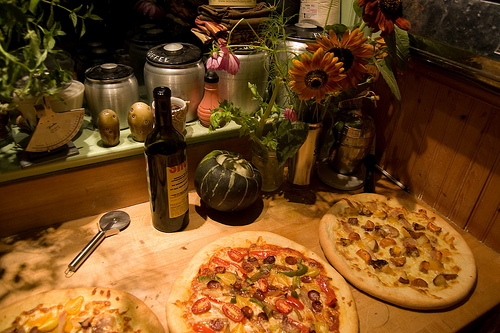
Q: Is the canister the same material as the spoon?
A: Yes, both the canister and the spoon are made of metal.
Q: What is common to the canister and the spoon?
A: The material, both the canister and the spoon are metallic.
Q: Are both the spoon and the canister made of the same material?
A: Yes, both the spoon and the canister are made of metal.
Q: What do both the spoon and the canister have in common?
A: The material, both the spoon and the canister are metallic.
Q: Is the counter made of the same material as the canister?
A: No, the counter is made of wood and the canister is made of metal.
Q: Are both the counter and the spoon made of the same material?
A: No, the counter is made of wood and the spoon is made of metal.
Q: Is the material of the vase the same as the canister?
A: No, the vase is made of glass and the canister is made of metal.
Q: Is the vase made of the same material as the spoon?
A: No, the vase is made of glass and the spoon is made of metal.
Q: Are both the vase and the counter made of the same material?
A: No, the vase is made of glass and the counter is made of wood.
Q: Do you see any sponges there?
A: No, there are no sponges.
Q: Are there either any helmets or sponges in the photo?
A: No, there are no sponges or helmets.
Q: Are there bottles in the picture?
A: Yes, there is a bottle.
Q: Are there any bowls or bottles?
A: Yes, there is a bottle.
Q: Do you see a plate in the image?
A: No, there are no plates.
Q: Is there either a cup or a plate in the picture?
A: No, there are no plates or cups.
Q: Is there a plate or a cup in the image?
A: No, there are no plates or cups.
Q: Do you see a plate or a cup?
A: No, there are no plates or cups.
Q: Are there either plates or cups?
A: No, there are no plates or cups.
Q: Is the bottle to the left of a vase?
A: Yes, the bottle is to the left of a vase.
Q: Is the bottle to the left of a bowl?
A: No, the bottle is to the left of a vase.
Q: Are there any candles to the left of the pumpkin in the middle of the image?
A: No, there is a bottle to the left of the pumpkin.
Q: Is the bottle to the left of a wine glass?
A: No, the bottle is to the left of the pumpkin.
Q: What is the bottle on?
A: The bottle is on the counter.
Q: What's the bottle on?
A: The bottle is on the counter.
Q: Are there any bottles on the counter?
A: Yes, there is a bottle on the counter.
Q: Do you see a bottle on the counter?
A: Yes, there is a bottle on the counter.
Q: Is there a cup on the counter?
A: No, there is a bottle on the counter.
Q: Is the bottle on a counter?
A: Yes, the bottle is on a counter.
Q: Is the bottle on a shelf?
A: No, the bottle is on a counter.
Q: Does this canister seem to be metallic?
A: Yes, the canister is metallic.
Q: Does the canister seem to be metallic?
A: Yes, the canister is metallic.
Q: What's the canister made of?
A: The canister is made of metal.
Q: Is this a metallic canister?
A: Yes, this is a metallic canister.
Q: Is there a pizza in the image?
A: Yes, there is a pizza.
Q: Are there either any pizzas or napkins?
A: Yes, there is a pizza.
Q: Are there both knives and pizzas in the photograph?
A: No, there is a pizza but no knives.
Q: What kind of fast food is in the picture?
A: The fast food is a pizza.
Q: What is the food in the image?
A: The food is a pizza.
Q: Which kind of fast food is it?
A: The food is a pizza.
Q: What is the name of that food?
A: This is a pizza.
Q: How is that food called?
A: This is a pizza.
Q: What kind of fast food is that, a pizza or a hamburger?
A: This is a pizza.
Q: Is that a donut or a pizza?
A: That is a pizza.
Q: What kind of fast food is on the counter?
A: The food is a pizza.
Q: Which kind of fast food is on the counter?
A: The food is a pizza.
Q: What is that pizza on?
A: The pizza is on the counter.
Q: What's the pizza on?
A: The pizza is on the counter.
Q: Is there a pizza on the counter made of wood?
A: Yes, there is a pizza on the counter.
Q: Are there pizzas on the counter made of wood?
A: Yes, there is a pizza on the counter.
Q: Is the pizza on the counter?
A: Yes, the pizza is on the counter.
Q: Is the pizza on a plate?
A: No, the pizza is on the counter.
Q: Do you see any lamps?
A: No, there are no lamps.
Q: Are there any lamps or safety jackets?
A: No, there are no lamps or safety jackets.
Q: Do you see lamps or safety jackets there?
A: No, there are no lamps or safety jackets.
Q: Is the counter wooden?
A: Yes, the counter is wooden.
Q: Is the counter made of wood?
A: Yes, the counter is made of wood.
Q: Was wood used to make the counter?
A: Yes, the counter is made of wood.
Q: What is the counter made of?
A: The counter is made of wood.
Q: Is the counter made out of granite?
A: No, the counter is made of wood.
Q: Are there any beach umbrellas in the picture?
A: No, there are no beach umbrellas.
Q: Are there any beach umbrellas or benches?
A: No, there are no beach umbrellas or benches.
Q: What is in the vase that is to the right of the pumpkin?
A: The flower is in the vase.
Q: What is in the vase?
A: The flower is in the vase.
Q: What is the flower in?
A: The flower is in the vase.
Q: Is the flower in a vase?
A: Yes, the flower is in a vase.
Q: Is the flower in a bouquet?
A: No, the flower is in a vase.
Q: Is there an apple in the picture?
A: No, there are no apples.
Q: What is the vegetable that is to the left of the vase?
A: The vegetable is a pumpkin.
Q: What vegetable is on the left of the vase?
A: The vegetable is a pumpkin.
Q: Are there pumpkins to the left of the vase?
A: Yes, there is a pumpkin to the left of the vase.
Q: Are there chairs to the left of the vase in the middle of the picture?
A: No, there is a pumpkin to the left of the vase.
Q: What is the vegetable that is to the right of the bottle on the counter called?
A: The vegetable is a pumpkin.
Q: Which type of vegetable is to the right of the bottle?
A: The vegetable is a pumpkin.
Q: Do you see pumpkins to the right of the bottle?
A: Yes, there is a pumpkin to the right of the bottle.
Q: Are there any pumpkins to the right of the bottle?
A: Yes, there is a pumpkin to the right of the bottle.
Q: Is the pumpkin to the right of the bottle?
A: Yes, the pumpkin is to the right of the bottle.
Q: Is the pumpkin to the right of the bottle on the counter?
A: Yes, the pumpkin is to the right of the bottle.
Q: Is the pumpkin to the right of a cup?
A: No, the pumpkin is to the right of the bottle.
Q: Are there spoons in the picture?
A: Yes, there is a spoon.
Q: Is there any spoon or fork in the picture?
A: Yes, there is a spoon.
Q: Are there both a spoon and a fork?
A: No, there is a spoon but no forks.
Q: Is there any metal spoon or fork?
A: Yes, there is a metal spoon.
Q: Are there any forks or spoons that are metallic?
A: Yes, the spoon is metallic.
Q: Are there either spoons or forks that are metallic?
A: Yes, the spoon is metallic.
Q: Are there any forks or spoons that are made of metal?
A: Yes, the spoon is made of metal.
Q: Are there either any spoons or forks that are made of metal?
A: Yes, the spoon is made of metal.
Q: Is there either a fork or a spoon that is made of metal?
A: Yes, the spoon is made of metal.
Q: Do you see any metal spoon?
A: Yes, there is a spoon that is made of metal.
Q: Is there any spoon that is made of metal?
A: Yes, there is a spoon that is made of metal.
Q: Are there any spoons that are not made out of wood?
A: Yes, there is a spoon that is made of metal.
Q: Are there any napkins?
A: No, there are no napkins.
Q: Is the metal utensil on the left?
A: Yes, the spoon is on the left of the image.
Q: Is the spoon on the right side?
A: No, the spoon is on the left of the image.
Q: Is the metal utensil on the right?
A: No, the spoon is on the left of the image.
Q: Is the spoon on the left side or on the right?
A: The spoon is on the left of the image.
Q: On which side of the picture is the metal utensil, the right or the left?
A: The spoon is on the left of the image.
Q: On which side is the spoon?
A: The spoon is on the left of the image.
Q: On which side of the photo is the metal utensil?
A: The spoon is on the left of the image.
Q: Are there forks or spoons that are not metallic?
A: No, there is a spoon but it is metallic.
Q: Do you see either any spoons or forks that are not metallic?
A: No, there is a spoon but it is metallic.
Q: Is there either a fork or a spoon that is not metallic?
A: No, there is a spoon but it is metallic.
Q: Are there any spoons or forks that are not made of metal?
A: No, there is a spoon but it is made of metal.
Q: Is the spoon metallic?
A: Yes, the spoon is metallic.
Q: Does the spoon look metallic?
A: Yes, the spoon is metallic.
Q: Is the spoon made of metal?
A: Yes, the spoon is made of metal.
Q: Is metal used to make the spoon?
A: Yes, the spoon is made of metal.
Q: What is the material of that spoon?
A: The spoon is made of metal.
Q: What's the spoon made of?
A: The spoon is made of metal.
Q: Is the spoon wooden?
A: No, the spoon is metallic.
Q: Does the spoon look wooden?
A: No, the spoon is metallic.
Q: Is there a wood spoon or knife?
A: No, there is a spoon but it is metallic.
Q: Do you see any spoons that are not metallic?
A: No, there is a spoon but it is metallic.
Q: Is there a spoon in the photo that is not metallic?
A: No, there is a spoon but it is metallic.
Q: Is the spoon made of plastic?
A: No, the spoon is made of metal.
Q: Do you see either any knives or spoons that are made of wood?
A: No, there is a spoon but it is made of metal.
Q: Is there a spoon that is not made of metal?
A: No, there is a spoon but it is made of metal.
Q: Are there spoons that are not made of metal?
A: No, there is a spoon but it is made of metal.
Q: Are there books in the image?
A: No, there are no books.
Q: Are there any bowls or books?
A: No, there are no books or bowls.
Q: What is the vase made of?
A: The vase is made of glass.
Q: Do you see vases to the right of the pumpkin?
A: Yes, there is a vase to the right of the pumpkin.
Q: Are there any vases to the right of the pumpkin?
A: Yes, there is a vase to the right of the pumpkin.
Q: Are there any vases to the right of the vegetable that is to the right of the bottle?
A: Yes, there is a vase to the right of the pumpkin.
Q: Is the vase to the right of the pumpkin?
A: Yes, the vase is to the right of the pumpkin.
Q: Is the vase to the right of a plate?
A: No, the vase is to the right of the pumpkin.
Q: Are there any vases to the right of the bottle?
A: Yes, there is a vase to the right of the bottle.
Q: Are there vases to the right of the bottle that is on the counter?
A: Yes, there is a vase to the right of the bottle.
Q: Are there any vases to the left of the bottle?
A: No, the vase is to the right of the bottle.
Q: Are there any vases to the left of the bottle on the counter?
A: No, the vase is to the right of the bottle.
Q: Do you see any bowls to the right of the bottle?
A: No, there is a vase to the right of the bottle.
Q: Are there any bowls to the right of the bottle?
A: No, there is a vase to the right of the bottle.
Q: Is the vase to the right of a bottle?
A: Yes, the vase is to the right of a bottle.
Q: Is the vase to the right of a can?
A: No, the vase is to the right of a bottle.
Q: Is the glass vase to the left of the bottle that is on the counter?
A: No, the vase is to the right of the bottle.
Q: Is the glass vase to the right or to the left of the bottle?
A: The vase is to the right of the bottle.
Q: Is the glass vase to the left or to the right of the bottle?
A: The vase is to the right of the bottle.